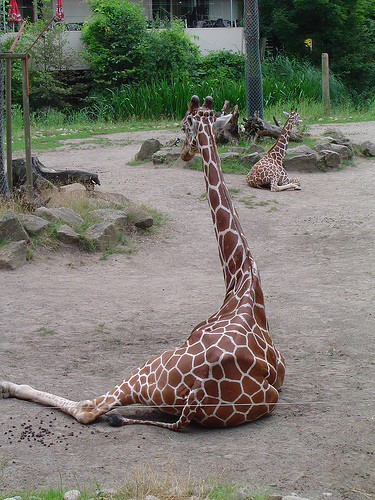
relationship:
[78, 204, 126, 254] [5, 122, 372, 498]
ground rocks on ground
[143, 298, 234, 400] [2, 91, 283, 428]
lines on animal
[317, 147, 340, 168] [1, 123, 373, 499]
rock on dirt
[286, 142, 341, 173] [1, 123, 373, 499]
boulder on dirt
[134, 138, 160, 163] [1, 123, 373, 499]
rock on dirt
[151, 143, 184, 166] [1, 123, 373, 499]
rock on dirt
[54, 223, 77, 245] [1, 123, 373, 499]
big rock on dirt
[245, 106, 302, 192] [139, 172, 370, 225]
animal on dirt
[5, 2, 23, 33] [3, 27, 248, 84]
umbrella on porch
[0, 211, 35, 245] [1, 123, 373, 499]
big rock on dirt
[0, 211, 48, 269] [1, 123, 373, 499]
big rock on dirt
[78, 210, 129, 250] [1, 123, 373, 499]
big rock on dirt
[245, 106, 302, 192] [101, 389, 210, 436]
animal has tail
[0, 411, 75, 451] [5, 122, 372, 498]
droppings on ground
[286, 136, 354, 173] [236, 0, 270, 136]
boulder near tree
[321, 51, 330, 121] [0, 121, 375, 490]
post along ground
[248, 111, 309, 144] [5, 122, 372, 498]
tree stump on ground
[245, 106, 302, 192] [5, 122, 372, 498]
animal on ground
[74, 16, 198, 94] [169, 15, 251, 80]
bush front wall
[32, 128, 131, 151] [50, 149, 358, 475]
grass growing on ground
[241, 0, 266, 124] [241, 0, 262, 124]
fence wrapped around fence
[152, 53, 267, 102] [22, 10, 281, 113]
plants growing on enclosure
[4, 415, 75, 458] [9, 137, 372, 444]
droppings on ground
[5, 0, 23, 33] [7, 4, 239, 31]
umbrella on patio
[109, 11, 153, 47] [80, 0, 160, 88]
leaves on tree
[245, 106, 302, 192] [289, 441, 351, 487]
animal on ground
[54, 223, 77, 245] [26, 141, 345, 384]
big rock on ground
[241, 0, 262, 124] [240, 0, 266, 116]
fence around tree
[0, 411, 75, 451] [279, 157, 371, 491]
droppings on ground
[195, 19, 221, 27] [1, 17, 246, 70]
furniture on porch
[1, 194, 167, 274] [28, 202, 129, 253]
grass growing out of rocks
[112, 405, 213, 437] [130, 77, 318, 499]
tail of giraffe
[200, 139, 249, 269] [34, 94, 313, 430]
neck of giraffe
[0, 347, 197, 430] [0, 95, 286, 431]
leg of animal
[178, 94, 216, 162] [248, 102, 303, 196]
head of giraffe